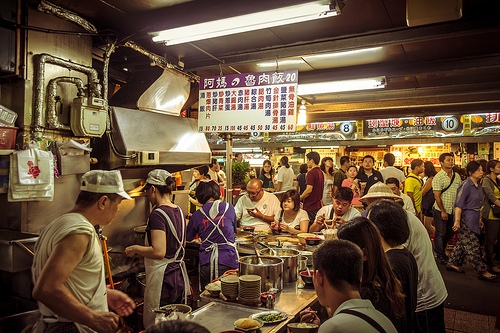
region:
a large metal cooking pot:
[238, 254, 284, 295]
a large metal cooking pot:
[262, 245, 299, 288]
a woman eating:
[271, 189, 308, 235]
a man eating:
[310, 189, 354, 231]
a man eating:
[235, 176, 277, 234]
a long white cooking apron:
[140, 203, 195, 329]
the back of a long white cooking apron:
[195, 201, 241, 278]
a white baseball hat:
[79, 167, 131, 200]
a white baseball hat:
[137, 170, 169, 186]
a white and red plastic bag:
[19, 151, 52, 186]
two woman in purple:
[134, 160, 247, 320]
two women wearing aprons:
[123, 167, 243, 314]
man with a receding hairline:
[230, 173, 279, 241]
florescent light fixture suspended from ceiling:
[147, 0, 342, 49]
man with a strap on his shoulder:
[308, 239, 405, 331]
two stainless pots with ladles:
[231, 240, 303, 289]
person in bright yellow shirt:
[400, 157, 432, 221]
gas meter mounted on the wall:
[63, 68, 115, 155]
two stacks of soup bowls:
[219, 270, 263, 304]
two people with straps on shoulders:
[402, 150, 464, 220]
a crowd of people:
[238, 143, 498, 240]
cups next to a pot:
[221, 270, 266, 304]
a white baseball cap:
[72, 164, 144, 207]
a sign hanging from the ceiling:
[197, 71, 313, 136]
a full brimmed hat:
[356, 176, 405, 204]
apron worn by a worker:
[138, 203, 191, 322]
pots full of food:
[239, 237, 301, 294]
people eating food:
[237, 172, 355, 239]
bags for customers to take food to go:
[3, 141, 70, 216]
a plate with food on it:
[248, 304, 293, 326]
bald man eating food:
[231, 163, 296, 254]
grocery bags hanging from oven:
[11, 130, 73, 215]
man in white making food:
[6, 145, 191, 312]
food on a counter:
[211, 291, 290, 331]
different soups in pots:
[231, 230, 305, 329]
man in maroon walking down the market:
[289, 145, 326, 224]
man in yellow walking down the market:
[392, 128, 449, 231]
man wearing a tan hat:
[340, 172, 425, 201]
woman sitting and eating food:
[321, 211, 413, 319]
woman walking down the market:
[254, 156, 286, 206]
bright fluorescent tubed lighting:
[145, 3, 356, 57]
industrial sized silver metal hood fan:
[96, 91, 218, 173]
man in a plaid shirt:
[421, 149, 461, 261]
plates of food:
[232, 306, 286, 331]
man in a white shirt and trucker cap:
[25, 167, 137, 331]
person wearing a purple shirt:
[184, 176, 239, 275]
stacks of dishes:
[200, 271, 271, 306]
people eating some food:
[235, 176, 358, 243]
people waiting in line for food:
[302, 171, 447, 331]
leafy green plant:
[222, 154, 257, 189]